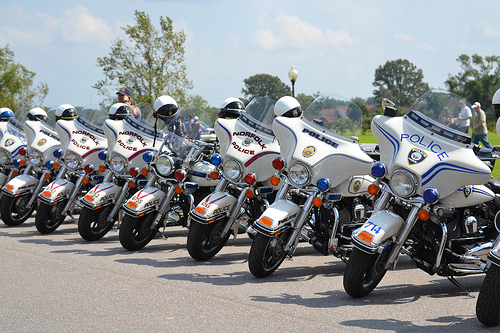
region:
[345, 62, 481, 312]
Police motorcycle is parked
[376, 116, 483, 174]
Police motorcycle has blue writing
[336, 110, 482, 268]
Police motorcycle is white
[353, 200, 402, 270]
Motorcycle has number 714 on fender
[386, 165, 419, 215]
Motorcycle headlight is off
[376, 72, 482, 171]
Motorcycle has clear bug shield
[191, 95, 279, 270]
Motorcycle belongs to Norfolk Police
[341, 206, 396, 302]
Motorcycle has orange light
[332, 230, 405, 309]
Motorcycle has black tire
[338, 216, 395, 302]
Motorcycle tire is rubber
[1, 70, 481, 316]
several police motorcycles in a line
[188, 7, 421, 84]
blue cloudy skies over a field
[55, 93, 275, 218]
Norfolk police motorcycles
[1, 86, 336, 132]
helmets placed on the handlebars of the motocycles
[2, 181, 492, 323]
black front wheels of the motorcycles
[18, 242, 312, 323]
grey asphalt of the road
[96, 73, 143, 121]
man standing behind the motocycles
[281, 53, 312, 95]
a street light in the park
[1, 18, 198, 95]
trees in the park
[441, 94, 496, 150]
two men walking through the park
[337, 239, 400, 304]
front wheel of bike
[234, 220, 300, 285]
front wheel of bike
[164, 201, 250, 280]
front wheel of bike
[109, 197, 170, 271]
front wheel of bike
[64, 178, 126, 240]
front wheel of bike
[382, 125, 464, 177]
blue police symbol on bike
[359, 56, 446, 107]
tree thats in back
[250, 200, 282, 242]
orange headlight of bike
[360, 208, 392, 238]
blue number on bike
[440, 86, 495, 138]
people walking in back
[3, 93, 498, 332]
row of motorcycles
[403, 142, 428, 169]
police badge on the front of the bike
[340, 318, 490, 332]
shadow on the ground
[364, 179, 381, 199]
small orange reflector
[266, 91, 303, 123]
large white helmet sitting on the handebar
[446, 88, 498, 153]
two men walking on the grass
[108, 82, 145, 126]
man wearing a blue hat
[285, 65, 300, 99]
light post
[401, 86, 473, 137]
small windshield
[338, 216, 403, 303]
black front wheel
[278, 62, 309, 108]
a street light near motorcycles.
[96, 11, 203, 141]
a tall green leafy tree.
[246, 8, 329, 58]
a white cloud in a blue sky.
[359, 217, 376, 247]
a light on the front of a bike.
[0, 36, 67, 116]
a tall leafy green tree.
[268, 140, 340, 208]
emergency response light.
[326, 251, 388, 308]
a front tire on a motorcycle.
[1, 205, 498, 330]
a section of paved road.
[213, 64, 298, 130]
a tall green tree.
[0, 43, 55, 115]
a tall branch filled tree.